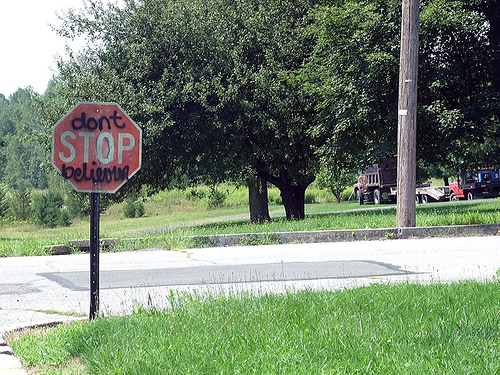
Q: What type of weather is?
A: It is sunny.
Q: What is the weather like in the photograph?
A: It is sunny.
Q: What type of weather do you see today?
A: It is sunny.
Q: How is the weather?
A: It is sunny.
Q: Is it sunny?
A: Yes, it is sunny.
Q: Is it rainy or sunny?
A: It is sunny.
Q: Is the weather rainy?
A: No, it is sunny.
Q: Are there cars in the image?
A: No, there are no cars.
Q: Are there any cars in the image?
A: No, there are no cars.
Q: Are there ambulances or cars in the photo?
A: No, there are no cars or ambulances.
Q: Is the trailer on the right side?
A: Yes, the trailer is on the right of the image.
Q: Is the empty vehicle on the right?
A: Yes, the trailer is on the right of the image.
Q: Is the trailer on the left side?
A: No, the trailer is on the right of the image.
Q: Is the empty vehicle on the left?
A: No, the trailer is on the right of the image.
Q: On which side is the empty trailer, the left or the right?
A: The trailer is on the right of the image.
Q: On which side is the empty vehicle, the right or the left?
A: The trailer is on the right of the image.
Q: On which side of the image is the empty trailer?
A: The trailer is on the right of the image.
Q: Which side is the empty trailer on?
A: The trailer is on the right of the image.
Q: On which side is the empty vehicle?
A: The trailer is on the right of the image.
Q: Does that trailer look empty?
A: Yes, the trailer is empty.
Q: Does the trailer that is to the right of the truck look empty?
A: Yes, the trailer is empty.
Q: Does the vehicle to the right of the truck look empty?
A: Yes, the trailer is empty.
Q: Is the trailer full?
A: No, the trailer is empty.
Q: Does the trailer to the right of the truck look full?
A: No, the trailer is empty.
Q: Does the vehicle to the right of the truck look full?
A: No, the trailer is empty.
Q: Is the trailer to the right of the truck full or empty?
A: The trailer is empty.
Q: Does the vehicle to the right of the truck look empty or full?
A: The trailer is empty.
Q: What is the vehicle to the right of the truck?
A: The vehicle is a trailer.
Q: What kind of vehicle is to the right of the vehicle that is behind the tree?
A: The vehicle is a trailer.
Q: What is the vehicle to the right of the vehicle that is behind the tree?
A: The vehicle is a trailer.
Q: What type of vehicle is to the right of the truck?
A: The vehicle is a trailer.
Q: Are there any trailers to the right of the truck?
A: Yes, there is a trailer to the right of the truck.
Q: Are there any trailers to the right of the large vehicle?
A: Yes, there is a trailer to the right of the truck.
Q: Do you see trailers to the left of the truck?
A: No, the trailer is to the right of the truck.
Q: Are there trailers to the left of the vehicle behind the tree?
A: No, the trailer is to the right of the truck.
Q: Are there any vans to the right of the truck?
A: No, there is a trailer to the right of the truck.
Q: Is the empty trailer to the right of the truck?
A: Yes, the trailer is to the right of the truck.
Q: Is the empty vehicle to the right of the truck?
A: Yes, the trailer is to the right of the truck.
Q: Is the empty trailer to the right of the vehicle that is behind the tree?
A: Yes, the trailer is to the right of the truck.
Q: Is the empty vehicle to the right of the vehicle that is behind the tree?
A: Yes, the trailer is to the right of the truck.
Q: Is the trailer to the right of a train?
A: No, the trailer is to the right of the truck.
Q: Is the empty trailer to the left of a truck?
A: No, the trailer is to the right of a truck.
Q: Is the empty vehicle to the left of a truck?
A: No, the trailer is to the right of a truck.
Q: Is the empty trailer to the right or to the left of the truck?
A: The trailer is to the right of the truck.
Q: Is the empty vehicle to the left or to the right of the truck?
A: The trailer is to the right of the truck.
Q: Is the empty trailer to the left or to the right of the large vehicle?
A: The trailer is to the right of the truck.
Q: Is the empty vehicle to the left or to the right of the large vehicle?
A: The trailer is to the right of the truck.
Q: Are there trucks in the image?
A: Yes, there is a truck.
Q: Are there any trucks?
A: Yes, there is a truck.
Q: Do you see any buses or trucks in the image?
A: Yes, there is a truck.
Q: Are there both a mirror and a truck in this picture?
A: No, there is a truck but no mirrors.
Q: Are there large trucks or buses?
A: Yes, there is a large truck.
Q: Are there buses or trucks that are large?
A: Yes, the truck is large.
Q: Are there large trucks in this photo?
A: Yes, there is a large truck.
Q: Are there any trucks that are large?
A: Yes, there is a truck that is large.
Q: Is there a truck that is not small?
A: Yes, there is a large truck.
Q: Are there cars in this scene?
A: No, there are no cars.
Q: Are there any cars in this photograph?
A: No, there are no cars.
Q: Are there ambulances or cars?
A: No, there are no cars or ambulances.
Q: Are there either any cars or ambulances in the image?
A: No, there are no cars or ambulances.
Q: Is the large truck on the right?
A: Yes, the truck is on the right of the image.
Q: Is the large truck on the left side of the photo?
A: No, the truck is on the right of the image.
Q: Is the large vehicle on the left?
A: No, the truck is on the right of the image.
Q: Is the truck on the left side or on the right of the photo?
A: The truck is on the right of the image.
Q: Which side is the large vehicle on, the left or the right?
A: The truck is on the right of the image.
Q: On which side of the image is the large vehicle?
A: The truck is on the right of the image.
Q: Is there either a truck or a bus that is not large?
A: No, there is a truck but it is large.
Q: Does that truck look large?
A: Yes, the truck is large.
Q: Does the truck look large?
A: Yes, the truck is large.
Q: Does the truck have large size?
A: Yes, the truck is large.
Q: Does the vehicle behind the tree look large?
A: Yes, the truck is large.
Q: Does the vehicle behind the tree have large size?
A: Yes, the truck is large.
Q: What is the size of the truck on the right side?
A: The truck is large.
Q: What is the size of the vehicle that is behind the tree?
A: The truck is large.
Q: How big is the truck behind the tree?
A: The truck is large.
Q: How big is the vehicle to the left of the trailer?
A: The truck is large.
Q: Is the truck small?
A: No, the truck is large.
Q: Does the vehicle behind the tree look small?
A: No, the truck is large.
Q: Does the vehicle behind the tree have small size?
A: No, the truck is large.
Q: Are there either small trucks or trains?
A: No, there is a truck but it is large.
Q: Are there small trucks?
A: No, there is a truck but it is large.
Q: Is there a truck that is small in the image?
A: No, there is a truck but it is large.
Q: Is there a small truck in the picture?
A: No, there is a truck but it is large.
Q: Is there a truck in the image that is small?
A: No, there is a truck but it is large.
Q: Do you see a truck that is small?
A: No, there is a truck but it is large.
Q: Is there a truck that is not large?
A: No, there is a truck but it is large.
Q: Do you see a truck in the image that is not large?
A: No, there is a truck but it is large.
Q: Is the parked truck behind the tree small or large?
A: The truck is large.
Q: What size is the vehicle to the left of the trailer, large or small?
A: The truck is large.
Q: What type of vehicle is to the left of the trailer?
A: The vehicle is a truck.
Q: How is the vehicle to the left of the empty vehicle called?
A: The vehicle is a truck.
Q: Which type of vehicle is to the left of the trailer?
A: The vehicle is a truck.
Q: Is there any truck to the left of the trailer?
A: Yes, there is a truck to the left of the trailer.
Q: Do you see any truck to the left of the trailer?
A: Yes, there is a truck to the left of the trailer.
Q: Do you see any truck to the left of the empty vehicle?
A: Yes, there is a truck to the left of the trailer.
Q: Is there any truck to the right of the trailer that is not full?
A: No, the truck is to the left of the trailer.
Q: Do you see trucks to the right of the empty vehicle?
A: No, the truck is to the left of the trailer.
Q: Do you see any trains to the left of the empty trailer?
A: No, there is a truck to the left of the trailer.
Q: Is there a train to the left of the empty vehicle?
A: No, there is a truck to the left of the trailer.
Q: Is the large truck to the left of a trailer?
A: Yes, the truck is to the left of a trailer.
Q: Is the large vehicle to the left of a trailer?
A: Yes, the truck is to the left of a trailer.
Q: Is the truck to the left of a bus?
A: No, the truck is to the left of a trailer.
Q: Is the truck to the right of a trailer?
A: No, the truck is to the left of a trailer.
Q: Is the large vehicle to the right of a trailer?
A: No, the truck is to the left of a trailer.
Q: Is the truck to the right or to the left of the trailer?
A: The truck is to the left of the trailer.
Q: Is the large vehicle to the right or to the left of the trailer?
A: The truck is to the left of the trailer.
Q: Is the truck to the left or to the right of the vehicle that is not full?
A: The truck is to the left of the trailer.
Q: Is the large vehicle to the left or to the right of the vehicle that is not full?
A: The truck is to the left of the trailer.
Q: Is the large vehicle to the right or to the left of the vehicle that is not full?
A: The truck is to the left of the trailer.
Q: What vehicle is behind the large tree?
A: The vehicle is a truck.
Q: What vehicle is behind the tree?
A: The vehicle is a truck.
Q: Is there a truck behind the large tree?
A: Yes, there is a truck behind the tree.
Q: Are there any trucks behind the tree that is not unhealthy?
A: Yes, there is a truck behind the tree.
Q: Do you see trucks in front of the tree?
A: No, the truck is behind the tree.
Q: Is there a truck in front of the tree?
A: No, the truck is behind the tree.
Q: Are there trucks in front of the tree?
A: No, the truck is behind the tree.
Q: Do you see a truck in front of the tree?
A: No, the truck is behind the tree.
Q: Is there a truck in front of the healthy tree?
A: No, the truck is behind the tree.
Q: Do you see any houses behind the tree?
A: No, there is a truck behind the tree.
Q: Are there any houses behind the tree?
A: No, there is a truck behind the tree.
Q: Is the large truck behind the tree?
A: Yes, the truck is behind the tree.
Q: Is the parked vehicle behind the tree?
A: Yes, the truck is behind the tree.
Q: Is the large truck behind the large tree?
A: Yes, the truck is behind the tree.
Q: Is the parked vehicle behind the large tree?
A: Yes, the truck is behind the tree.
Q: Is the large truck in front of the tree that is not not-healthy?
A: No, the truck is behind the tree.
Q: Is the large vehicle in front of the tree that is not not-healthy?
A: No, the truck is behind the tree.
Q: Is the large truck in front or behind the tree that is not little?
A: The truck is behind the tree.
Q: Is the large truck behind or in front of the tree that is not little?
A: The truck is behind the tree.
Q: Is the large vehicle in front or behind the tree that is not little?
A: The truck is behind the tree.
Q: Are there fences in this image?
A: No, there are no fences.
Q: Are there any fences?
A: No, there are no fences.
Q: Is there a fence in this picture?
A: No, there are no fences.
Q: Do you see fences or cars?
A: No, there are no fences or cars.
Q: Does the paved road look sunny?
A: Yes, the road is sunny.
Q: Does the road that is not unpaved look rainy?
A: No, the road is sunny.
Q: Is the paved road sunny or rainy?
A: The road is sunny.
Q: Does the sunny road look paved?
A: Yes, the road is paved.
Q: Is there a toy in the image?
A: No, there are no toys.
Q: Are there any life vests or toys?
A: No, there are no toys or life vests.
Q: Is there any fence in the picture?
A: No, there are no fences.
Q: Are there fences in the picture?
A: No, there are no fences.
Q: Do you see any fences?
A: No, there are no fences.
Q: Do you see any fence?
A: No, there are no fences.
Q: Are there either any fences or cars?
A: No, there are no fences or cars.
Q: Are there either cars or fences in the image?
A: No, there are no fences or cars.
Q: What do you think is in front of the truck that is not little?
A: The tree is in front of the truck.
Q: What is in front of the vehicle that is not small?
A: The tree is in front of the truck.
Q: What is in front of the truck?
A: The tree is in front of the truck.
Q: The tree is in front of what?
A: The tree is in front of the truck.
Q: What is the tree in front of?
A: The tree is in front of the truck.